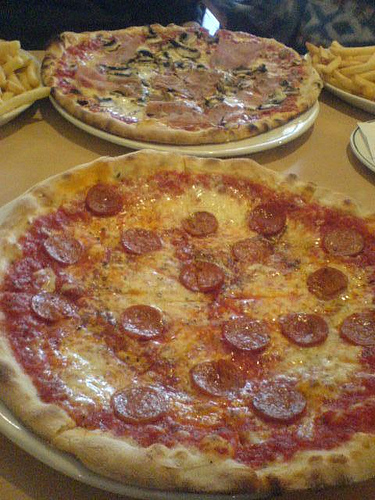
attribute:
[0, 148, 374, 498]
pizza — large, great, beautiful, burned, circular, rounded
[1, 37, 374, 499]
table — wooden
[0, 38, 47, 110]
fries — delicious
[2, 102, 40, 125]
plate — white, porcelain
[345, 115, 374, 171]
plate — empty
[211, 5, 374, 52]
shirt — blue, white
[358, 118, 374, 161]
napkin — white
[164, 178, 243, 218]
cheese — melted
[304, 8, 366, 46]
pattern — nice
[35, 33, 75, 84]
crust — burned